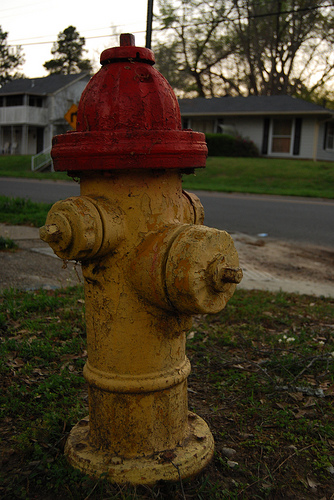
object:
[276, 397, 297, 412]
leaf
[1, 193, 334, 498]
ground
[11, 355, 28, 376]
leaf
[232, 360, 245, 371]
leaf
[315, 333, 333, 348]
leaf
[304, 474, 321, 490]
leaf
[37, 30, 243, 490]
fire hydrant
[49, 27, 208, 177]
top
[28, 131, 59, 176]
hand rail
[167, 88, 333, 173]
house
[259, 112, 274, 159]
shutter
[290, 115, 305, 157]
shutter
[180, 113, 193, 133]
shutter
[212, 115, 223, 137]
shutter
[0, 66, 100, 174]
house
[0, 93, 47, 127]
porch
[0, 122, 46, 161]
porch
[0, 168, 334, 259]
roadway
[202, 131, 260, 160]
hedge bush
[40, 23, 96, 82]
tree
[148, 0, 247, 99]
tree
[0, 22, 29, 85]
tree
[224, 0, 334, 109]
tree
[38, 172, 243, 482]
bottom portion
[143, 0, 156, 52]
utility pole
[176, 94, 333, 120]
roof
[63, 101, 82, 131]
traffic sign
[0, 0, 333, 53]
power line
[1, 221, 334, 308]
sidewalk